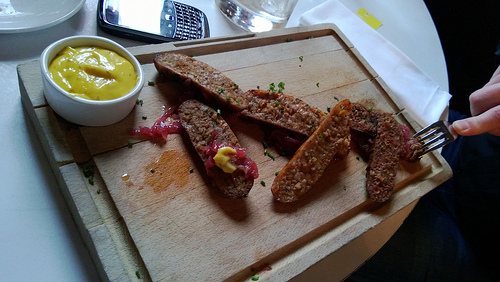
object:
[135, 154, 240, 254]
board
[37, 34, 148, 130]
bowl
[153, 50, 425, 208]
brown meat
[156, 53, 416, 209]
slices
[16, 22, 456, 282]
cutting board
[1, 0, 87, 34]
plate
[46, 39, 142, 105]
dish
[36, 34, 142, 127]
white dish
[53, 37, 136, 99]
yellow sauce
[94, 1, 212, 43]
blackberry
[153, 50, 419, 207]
sausage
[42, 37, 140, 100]
mustard